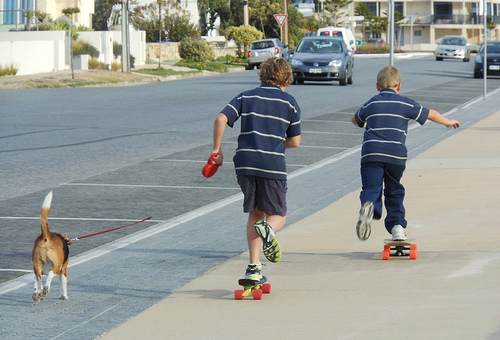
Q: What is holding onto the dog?
A: Leash.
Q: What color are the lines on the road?
A: White.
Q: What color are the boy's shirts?
A: Blue and White.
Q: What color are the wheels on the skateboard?
A: Red.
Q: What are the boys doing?
A: Skateboarding.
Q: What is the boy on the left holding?
A: A leash.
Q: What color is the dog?
A: Black, brown and white.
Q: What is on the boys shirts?
A: Stripes.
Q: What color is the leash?
A: Red.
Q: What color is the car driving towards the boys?
A: Silver.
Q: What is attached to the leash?
A: A dog.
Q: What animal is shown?
A: Dog.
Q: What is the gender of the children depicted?
A: Male.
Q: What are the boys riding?
A: Skateboards.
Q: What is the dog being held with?
A: Leash.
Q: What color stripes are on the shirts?
A: White.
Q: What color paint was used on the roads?
A: White.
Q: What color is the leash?
A: Red.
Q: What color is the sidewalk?
A: Brown.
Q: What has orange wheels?
A: Skateboards.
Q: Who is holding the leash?
A: The left boy.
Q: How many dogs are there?
A: 1.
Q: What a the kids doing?
A: Riding skateboards.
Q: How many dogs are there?
A: One.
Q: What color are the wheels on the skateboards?
A: Orange.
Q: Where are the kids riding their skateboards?
A: Sidewalk.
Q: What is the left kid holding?
A: A dog leash.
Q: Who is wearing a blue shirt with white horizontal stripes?
A: Both kids.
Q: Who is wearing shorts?
A: The kid on the left.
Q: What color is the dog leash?
A: Red.